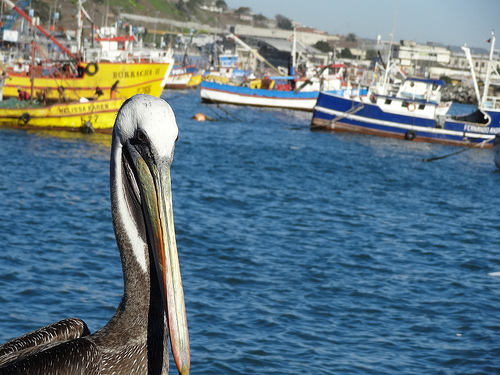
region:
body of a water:
[21, 187, 84, 237]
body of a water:
[205, 277, 291, 347]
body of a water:
[375, 296, 415, 366]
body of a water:
[440, 297, 490, 352]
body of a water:
[436, 175, 487, 216]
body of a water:
[300, 170, 345, 230]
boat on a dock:
[310, 46, 495, 176]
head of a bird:
[92, 68, 219, 208]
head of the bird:
[50, 72, 221, 211]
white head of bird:
[103, 85, 199, 175]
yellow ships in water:
[38, 58, 111, 138]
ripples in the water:
[213, 224, 363, 345]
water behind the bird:
[265, 193, 384, 282]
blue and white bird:
[281, 75, 454, 180]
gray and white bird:
[26, 73, 202, 372]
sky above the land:
[368, 2, 465, 43]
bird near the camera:
[0, 94, 187, 374]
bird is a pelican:
[2, 95, 191, 374]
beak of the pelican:
[129, 142, 189, 374]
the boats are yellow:
[2, 60, 169, 125]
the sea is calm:
[2, 83, 499, 374]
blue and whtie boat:
[316, 79, 498, 145]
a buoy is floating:
[194, 112, 206, 121]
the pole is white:
[481, 33, 493, 110]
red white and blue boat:
[201, 75, 364, 106]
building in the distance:
[395, 40, 450, 63]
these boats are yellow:
[11, 55, 223, 149]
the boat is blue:
[298, 53, 496, 154]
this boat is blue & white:
[201, 78, 353, 125]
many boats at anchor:
[28, 7, 498, 167]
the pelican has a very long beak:
[97, 92, 228, 367]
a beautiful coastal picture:
[25, 12, 484, 367]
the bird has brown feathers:
[21, 325, 64, 369]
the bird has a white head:
[113, 95, 181, 161]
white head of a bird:
[110, 88, 177, 167]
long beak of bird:
[125, 155, 198, 370]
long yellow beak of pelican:
[128, 157, 216, 372]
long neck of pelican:
[8, 81, 207, 372]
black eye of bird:
[120, 125, 155, 156]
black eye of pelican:
[119, 124, 149, 154]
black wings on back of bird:
[31, 310, 110, 374]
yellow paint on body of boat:
[2, 58, 157, 127]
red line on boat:
[27, 81, 110, 93]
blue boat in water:
[320, 82, 489, 159]